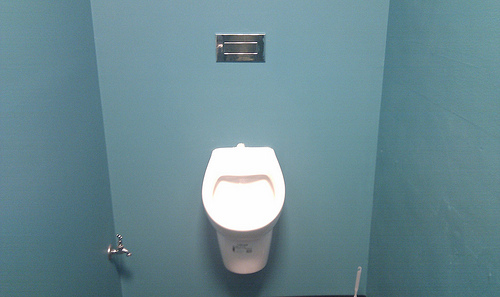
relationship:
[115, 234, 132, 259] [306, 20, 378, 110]
spigot on wall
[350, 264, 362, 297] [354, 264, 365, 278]
brush has a handle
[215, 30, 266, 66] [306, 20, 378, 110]
object on wall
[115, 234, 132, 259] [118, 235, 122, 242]
spigot has a knob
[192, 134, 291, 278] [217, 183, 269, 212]
urinal has a bowl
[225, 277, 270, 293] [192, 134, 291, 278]
shadow on bottom of urinal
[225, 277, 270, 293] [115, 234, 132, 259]
shadow under spigot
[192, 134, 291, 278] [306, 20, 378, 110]
urinal on wall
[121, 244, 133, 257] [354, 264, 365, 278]
spout has a handle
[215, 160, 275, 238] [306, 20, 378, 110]
toilet on wall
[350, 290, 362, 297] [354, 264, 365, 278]
brush has a handle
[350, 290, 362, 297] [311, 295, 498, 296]
brush on floor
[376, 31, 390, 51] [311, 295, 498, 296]
trim on floor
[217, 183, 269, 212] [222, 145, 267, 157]
bowl of tank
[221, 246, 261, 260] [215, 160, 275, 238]
logo on toilet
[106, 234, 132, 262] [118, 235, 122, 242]
spigot has a knob